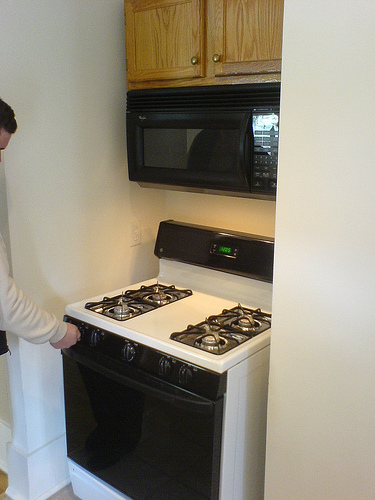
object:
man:
[0, 99, 70, 499]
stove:
[61, 219, 275, 499]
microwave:
[125, 91, 283, 196]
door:
[61, 378, 223, 498]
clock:
[218, 246, 231, 254]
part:
[154, 218, 272, 284]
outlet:
[130, 222, 141, 245]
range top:
[65, 280, 268, 376]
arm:
[0, 249, 62, 343]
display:
[210, 243, 239, 260]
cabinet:
[125, 0, 284, 84]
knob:
[191, 56, 198, 66]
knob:
[212, 54, 221, 64]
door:
[126, 1, 206, 85]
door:
[213, 3, 281, 75]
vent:
[125, 85, 280, 110]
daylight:
[250, 114, 279, 157]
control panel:
[252, 113, 276, 194]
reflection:
[80, 363, 145, 476]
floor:
[47, 482, 78, 500]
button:
[255, 130, 262, 136]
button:
[262, 131, 269, 135]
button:
[268, 129, 277, 137]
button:
[252, 145, 265, 153]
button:
[262, 148, 270, 153]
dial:
[72, 324, 84, 344]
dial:
[122, 344, 134, 363]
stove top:
[67, 274, 272, 358]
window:
[65, 350, 227, 498]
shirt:
[0, 221, 69, 343]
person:
[0, 100, 80, 490]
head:
[0, 97, 19, 163]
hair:
[0, 96, 19, 134]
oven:
[65, 215, 274, 498]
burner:
[131, 280, 190, 306]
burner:
[90, 294, 146, 322]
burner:
[214, 302, 272, 334]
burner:
[176, 322, 243, 354]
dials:
[157, 352, 171, 377]